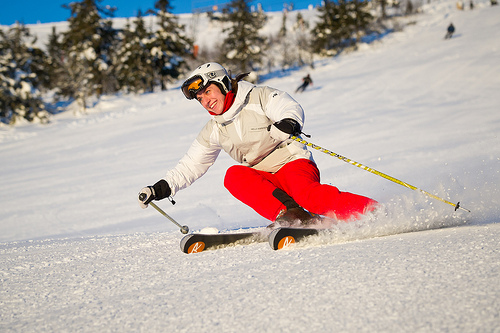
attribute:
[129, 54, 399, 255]
skier — kicking, happy, skiing, leaning, smiling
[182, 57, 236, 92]
helmet — white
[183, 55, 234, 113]
head — skier's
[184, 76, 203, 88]
glass — yellow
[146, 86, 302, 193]
coat — white, winter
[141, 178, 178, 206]
glove — black, white, dark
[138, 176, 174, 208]
hand — skier's, gloved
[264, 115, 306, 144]
glove — black, white, dark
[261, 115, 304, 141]
hand — skier's, gloved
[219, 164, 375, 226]
pants — red, bright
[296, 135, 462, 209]
pole — yellow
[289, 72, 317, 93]
skier — skiing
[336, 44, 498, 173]
hill — snow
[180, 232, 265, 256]
ski — black, bright, blue, person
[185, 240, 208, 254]
logo — golden, orange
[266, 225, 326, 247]
ski — black, bright, blue, person's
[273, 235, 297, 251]
logo — golden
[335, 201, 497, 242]
snow — kicked, white, fluffy, flying, spraying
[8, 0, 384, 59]
trees — snowy, coniferous, cluster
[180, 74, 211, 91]
lense — orange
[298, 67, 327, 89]
people — skiing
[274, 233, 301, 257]
emblem — orange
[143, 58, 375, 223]
person — out, skiing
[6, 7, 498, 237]
day — clear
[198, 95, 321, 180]
jacket — white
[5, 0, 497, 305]
air — cold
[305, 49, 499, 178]
slope — snowy